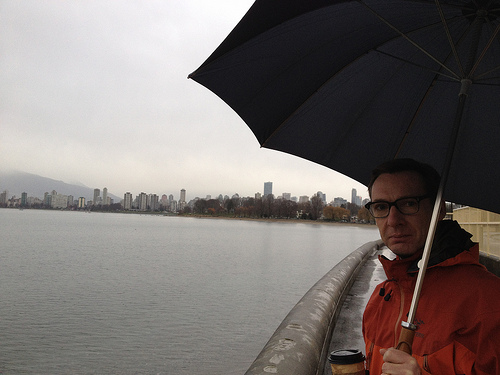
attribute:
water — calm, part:
[84, 264, 137, 290]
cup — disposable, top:
[315, 332, 357, 372]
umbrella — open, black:
[209, 8, 459, 120]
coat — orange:
[429, 271, 468, 326]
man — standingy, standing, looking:
[346, 141, 478, 374]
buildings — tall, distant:
[0, 175, 190, 218]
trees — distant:
[202, 200, 246, 218]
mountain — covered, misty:
[2, 164, 75, 192]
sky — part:
[111, 0, 139, 38]